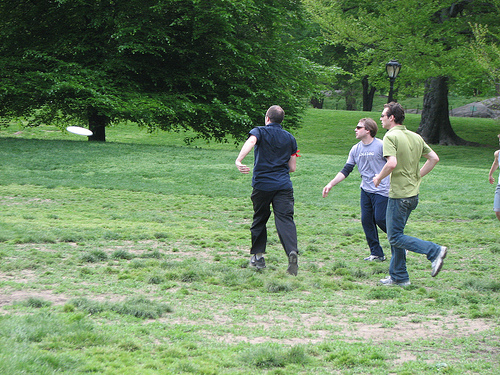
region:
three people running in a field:
[232, 83, 453, 305]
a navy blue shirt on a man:
[246, 123, 296, 203]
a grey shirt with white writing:
[344, 140, 395, 209]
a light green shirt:
[382, 126, 429, 209]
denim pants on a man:
[387, 197, 437, 284]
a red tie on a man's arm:
[291, 145, 300, 162]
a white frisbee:
[62, 118, 96, 153]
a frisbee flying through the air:
[65, 106, 94, 151]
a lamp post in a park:
[369, 33, 411, 113]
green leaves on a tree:
[96, 26, 179, 79]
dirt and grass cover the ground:
[35, 240, 335, 371]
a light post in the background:
[367, 50, 419, 104]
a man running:
[232, 110, 313, 260]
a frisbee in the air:
[32, 93, 112, 158]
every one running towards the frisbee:
[39, 67, 499, 266]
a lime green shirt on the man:
[376, 128, 444, 213]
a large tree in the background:
[20, 3, 262, 118]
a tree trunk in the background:
[421, 7, 451, 149]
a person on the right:
[480, 137, 498, 191]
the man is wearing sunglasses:
[350, 118, 378, 137]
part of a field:
[318, 339, 333, 361]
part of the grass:
[145, 258, 169, 327]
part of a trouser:
[280, 238, 292, 245]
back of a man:
[262, 153, 275, 170]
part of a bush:
[198, 88, 205, 109]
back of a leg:
[281, 208, 283, 239]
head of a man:
[263, 102, 281, 135]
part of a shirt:
[370, 133, 377, 151]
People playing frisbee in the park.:
[208, 79, 441, 293]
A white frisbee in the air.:
[61, 117, 88, 161]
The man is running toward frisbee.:
[226, 103, 326, 254]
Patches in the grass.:
[72, 270, 175, 335]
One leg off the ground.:
[398, 228, 446, 268]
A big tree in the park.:
[57, 24, 277, 127]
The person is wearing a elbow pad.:
[332, 155, 367, 189]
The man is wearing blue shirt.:
[228, 125, 280, 187]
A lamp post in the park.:
[384, 47, 404, 124]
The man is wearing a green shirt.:
[375, 138, 428, 180]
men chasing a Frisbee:
[235, 102, 450, 283]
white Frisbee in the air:
[67, 122, 91, 137]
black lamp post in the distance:
[386, 63, 397, 104]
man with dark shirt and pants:
[233, 103, 297, 273]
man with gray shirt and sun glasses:
[320, 120, 389, 262]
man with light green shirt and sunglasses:
[369, 102, 448, 287]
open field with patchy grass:
[7, 139, 499, 369]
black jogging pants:
[250, 188, 299, 256]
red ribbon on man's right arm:
[292, 147, 303, 157]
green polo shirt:
[385, 125, 428, 196]